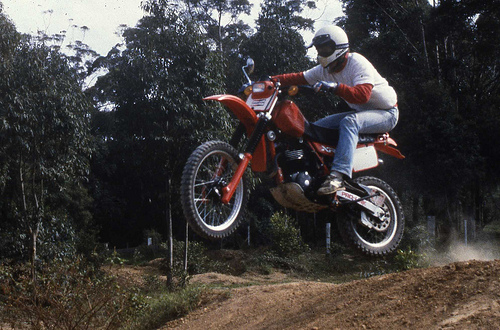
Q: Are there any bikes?
A: Yes, there is a bike.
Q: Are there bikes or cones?
A: Yes, there is a bike.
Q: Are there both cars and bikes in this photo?
A: No, there is a bike but no cars.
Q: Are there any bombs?
A: No, there are no bombs.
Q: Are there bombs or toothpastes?
A: No, there are no bombs or toothpastes.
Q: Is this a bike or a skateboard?
A: This is a bike.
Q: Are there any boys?
A: No, there are no boys.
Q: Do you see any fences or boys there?
A: No, there are no boys or fences.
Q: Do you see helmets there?
A: Yes, there is a helmet.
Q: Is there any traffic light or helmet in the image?
A: Yes, there is a helmet.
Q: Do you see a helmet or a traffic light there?
A: Yes, there is a helmet.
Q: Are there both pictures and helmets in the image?
A: No, there is a helmet but no pictures.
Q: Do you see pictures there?
A: No, there are no pictures.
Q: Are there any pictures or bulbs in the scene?
A: No, there are no pictures or bulbs.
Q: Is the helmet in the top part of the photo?
A: Yes, the helmet is in the top of the image.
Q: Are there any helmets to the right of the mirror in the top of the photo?
A: Yes, there is a helmet to the right of the mirror.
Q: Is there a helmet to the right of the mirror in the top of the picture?
A: Yes, there is a helmet to the right of the mirror.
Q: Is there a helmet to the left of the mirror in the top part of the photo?
A: No, the helmet is to the right of the mirror.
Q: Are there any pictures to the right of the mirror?
A: No, there is a helmet to the right of the mirror.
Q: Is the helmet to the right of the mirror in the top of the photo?
A: Yes, the helmet is to the right of the mirror.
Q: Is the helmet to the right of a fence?
A: No, the helmet is to the right of the mirror.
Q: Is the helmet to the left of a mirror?
A: No, the helmet is to the right of a mirror.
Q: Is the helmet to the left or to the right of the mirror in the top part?
A: The helmet is to the right of the mirror.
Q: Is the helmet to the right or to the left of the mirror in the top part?
A: The helmet is to the right of the mirror.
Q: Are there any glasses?
A: No, there are no glasses.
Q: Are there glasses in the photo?
A: No, there are no glasses.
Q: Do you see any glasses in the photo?
A: No, there are no glasses.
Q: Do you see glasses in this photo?
A: No, there are no glasses.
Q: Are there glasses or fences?
A: No, there are no glasses or fences.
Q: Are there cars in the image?
A: No, there are no cars.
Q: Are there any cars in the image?
A: No, there are no cars.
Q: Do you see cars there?
A: No, there are no cars.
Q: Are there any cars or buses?
A: No, there are no cars or buses.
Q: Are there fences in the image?
A: No, there are no fences.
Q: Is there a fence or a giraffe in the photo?
A: No, there are no fences or giraffes.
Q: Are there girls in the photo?
A: No, there are no girls.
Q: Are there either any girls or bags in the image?
A: No, there are no girls or bags.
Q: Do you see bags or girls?
A: No, there are no girls or bags.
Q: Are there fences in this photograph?
A: No, there are no fences.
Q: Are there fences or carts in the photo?
A: No, there are no fences or carts.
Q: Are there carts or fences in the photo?
A: No, there are no fences or carts.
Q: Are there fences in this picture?
A: No, there are no fences.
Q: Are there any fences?
A: No, there are no fences.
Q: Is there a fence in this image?
A: No, there are no fences.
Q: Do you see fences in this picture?
A: No, there are no fences.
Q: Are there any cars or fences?
A: No, there are no fences or cars.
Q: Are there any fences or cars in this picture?
A: No, there are no fences or cars.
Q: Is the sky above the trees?
A: Yes, the sky is above the trees.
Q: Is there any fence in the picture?
A: No, there are no fences.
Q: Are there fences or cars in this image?
A: No, there are no fences or cars.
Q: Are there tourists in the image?
A: No, there are no tourists.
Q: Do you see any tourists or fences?
A: No, there are no tourists or fences.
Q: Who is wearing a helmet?
A: The man is wearing a helmet.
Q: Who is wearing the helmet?
A: The man is wearing a helmet.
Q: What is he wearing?
A: The man is wearing a helmet.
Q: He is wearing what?
A: The man is wearing a helmet.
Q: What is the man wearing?
A: The man is wearing a helmet.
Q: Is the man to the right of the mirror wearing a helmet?
A: Yes, the man is wearing a helmet.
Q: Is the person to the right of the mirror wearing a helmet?
A: Yes, the man is wearing a helmet.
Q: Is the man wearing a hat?
A: No, the man is wearing a helmet.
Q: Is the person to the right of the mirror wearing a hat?
A: No, the man is wearing a helmet.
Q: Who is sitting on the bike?
A: The man is sitting on the bike.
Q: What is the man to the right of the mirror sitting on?
A: The man is sitting on the bike.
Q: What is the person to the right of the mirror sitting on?
A: The man is sitting on the bike.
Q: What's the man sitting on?
A: The man is sitting on the bike.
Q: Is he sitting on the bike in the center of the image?
A: Yes, the man is sitting on the bike.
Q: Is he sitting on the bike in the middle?
A: Yes, the man is sitting on the bike.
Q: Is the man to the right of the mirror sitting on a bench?
A: No, the man is sitting on the bike.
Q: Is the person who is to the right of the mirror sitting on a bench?
A: No, the man is sitting on the bike.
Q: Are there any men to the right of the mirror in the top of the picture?
A: Yes, there is a man to the right of the mirror.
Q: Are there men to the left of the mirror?
A: No, the man is to the right of the mirror.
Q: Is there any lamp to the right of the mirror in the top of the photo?
A: No, there is a man to the right of the mirror.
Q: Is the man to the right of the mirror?
A: Yes, the man is to the right of the mirror.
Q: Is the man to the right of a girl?
A: No, the man is to the right of the mirror.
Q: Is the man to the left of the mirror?
A: No, the man is to the right of the mirror.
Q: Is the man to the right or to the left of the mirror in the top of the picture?
A: The man is to the right of the mirror.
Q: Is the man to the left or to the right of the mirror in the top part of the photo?
A: The man is to the right of the mirror.